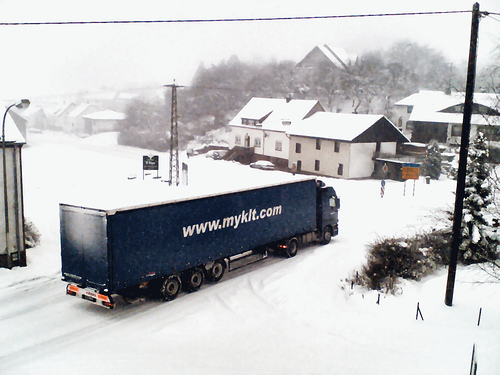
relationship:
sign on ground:
[137, 150, 162, 181] [23, 124, 267, 235]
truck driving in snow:
[60, 178, 338, 310] [272, 302, 313, 350]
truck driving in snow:
[60, 178, 338, 310] [245, 273, 315, 327]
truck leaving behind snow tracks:
[60, 178, 338, 310] [9, 283, 69, 359]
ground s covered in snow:
[114, 320, 338, 372] [224, 301, 295, 345]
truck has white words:
[60, 178, 338, 310] [174, 202, 291, 232]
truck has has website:
[60, 178, 338, 310] [180, 210, 299, 235]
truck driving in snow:
[57, 154, 348, 315] [351, 183, 447, 220]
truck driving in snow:
[60, 178, 338, 310] [55, 160, 481, 286]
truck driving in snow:
[60, 178, 338, 310] [54, 146, 443, 363]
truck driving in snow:
[57, 154, 348, 315] [31, 171, 433, 372]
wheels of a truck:
[139, 251, 232, 310] [57, 154, 348, 315]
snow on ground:
[38, 316, 426, 373] [114, 310, 454, 366]